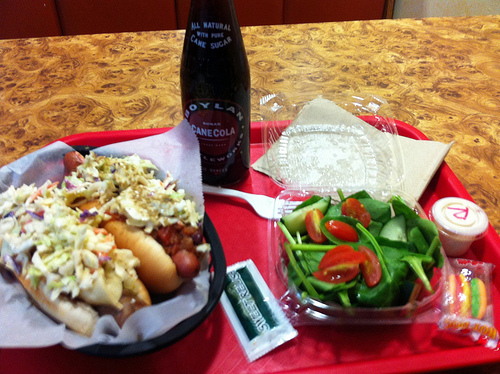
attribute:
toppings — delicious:
[80, 152, 195, 242]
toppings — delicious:
[11, 195, 116, 295]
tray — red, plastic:
[48, 125, 485, 373]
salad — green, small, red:
[282, 195, 432, 298]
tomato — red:
[302, 213, 343, 247]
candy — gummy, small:
[448, 268, 499, 333]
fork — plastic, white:
[197, 181, 278, 220]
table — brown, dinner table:
[4, 20, 499, 374]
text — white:
[195, 23, 231, 32]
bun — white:
[110, 224, 173, 281]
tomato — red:
[321, 245, 359, 270]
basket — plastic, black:
[95, 233, 228, 353]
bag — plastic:
[456, 258, 481, 276]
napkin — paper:
[265, 108, 442, 208]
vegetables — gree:
[351, 211, 407, 255]